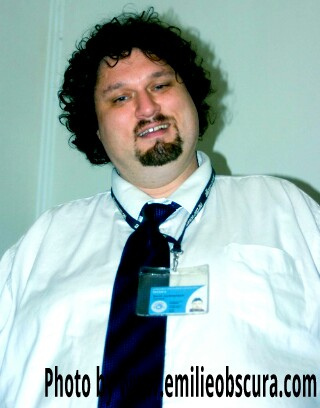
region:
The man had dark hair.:
[51, 7, 221, 128]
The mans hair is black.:
[45, 9, 221, 166]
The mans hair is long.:
[56, 6, 220, 160]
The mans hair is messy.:
[43, 11, 235, 178]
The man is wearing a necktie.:
[89, 202, 174, 406]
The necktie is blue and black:
[100, 202, 180, 400]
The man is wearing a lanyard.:
[109, 202, 239, 318]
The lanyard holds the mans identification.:
[123, 256, 229, 324]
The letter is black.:
[32, 359, 52, 395]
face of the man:
[59, 39, 213, 180]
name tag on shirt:
[127, 267, 223, 314]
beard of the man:
[139, 139, 179, 168]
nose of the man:
[126, 87, 158, 118]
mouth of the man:
[141, 124, 173, 138]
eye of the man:
[152, 76, 174, 95]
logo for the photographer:
[42, 363, 316, 396]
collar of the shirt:
[118, 179, 203, 218]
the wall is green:
[261, 54, 301, 139]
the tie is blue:
[120, 328, 148, 366]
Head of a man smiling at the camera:
[55, 3, 219, 179]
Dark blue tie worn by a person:
[96, 199, 181, 403]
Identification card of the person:
[136, 263, 211, 316]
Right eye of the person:
[108, 90, 131, 106]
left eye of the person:
[152, 81, 171, 91]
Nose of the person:
[135, 90, 160, 116]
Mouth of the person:
[132, 121, 172, 140]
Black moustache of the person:
[132, 112, 174, 134]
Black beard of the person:
[136, 138, 183, 167]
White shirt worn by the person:
[2, 151, 317, 407]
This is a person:
[29, 9, 317, 396]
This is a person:
[7, 8, 318, 392]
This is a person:
[16, 7, 315, 367]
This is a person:
[16, 12, 317, 402]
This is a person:
[13, 6, 316, 405]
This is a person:
[35, 6, 318, 402]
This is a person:
[11, 7, 319, 387]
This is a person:
[9, 4, 317, 367]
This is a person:
[16, 1, 294, 396]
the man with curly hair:
[28, 11, 246, 180]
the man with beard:
[109, 101, 189, 170]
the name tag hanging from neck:
[106, 173, 207, 321]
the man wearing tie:
[2, 12, 318, 401]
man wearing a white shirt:
[0, 145, 319, 406]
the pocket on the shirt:
[220, 232, 306, 341]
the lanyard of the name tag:
[99, 174, 213, 235]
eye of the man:
[99, 89, 136, 112]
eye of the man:
[136, 76, 169, 93]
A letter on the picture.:
[302, 372, 314, 393]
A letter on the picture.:
[282, 373, 294, 399]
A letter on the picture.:
[269, 373, 276, 394]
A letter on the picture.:
[263, 371, 268, 397]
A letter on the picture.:
[250, 373, 260, 397]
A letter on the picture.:
[242, 373, 256, 395]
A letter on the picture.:
[232, 373, 242, 394]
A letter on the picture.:
[225, 365, 236, 393]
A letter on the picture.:
[216, 372, 223, 394]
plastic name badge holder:
[124, 252, 218, 322]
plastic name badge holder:
[137, 263, 219, 323]